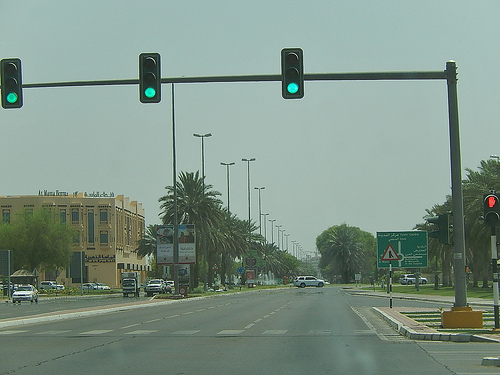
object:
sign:
[375, 231, 432, 271]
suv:
[291, 274, 331, 292]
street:
[2, 281, 493, 373]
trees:
[318, 220, 379, 289]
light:
[7, 92, 17, 101]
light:
[145, 87, 154, 95]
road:
[1, 285, 453, 374]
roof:
[23, 179, 143, 219]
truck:
[285, 269, 339, 294]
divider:
[153, 280, 300, 300]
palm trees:
[156, 168, 302, 280]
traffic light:
[424, 205, 466, 259]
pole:
[445, 59, 467, 330]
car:
[13, 283, 38, 310]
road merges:
[217, 264, 312, 365]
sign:
[378, 235, 405, 267]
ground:
[423, 108, 440, 140]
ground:
[381, 120, 421, 144]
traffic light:
[280, 47, 308, 99]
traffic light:
[141, 53, 162, 100]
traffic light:
[1, 55, 22, 105]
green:
[282, 80, 297, 93]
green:
[7, 89, 17, 105]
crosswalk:
[0, 310, 385, 338]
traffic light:
[481, 191, 499, 235]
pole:
[487, 228, 499, 328]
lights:
[190, 128, 316, 269]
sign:
[477, 186, 497, 214]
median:
[0, 275, 285, 328]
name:
[37, 186, 122, 200]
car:
[288, 267, 329, 295]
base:
[434, 300, 484, 328]